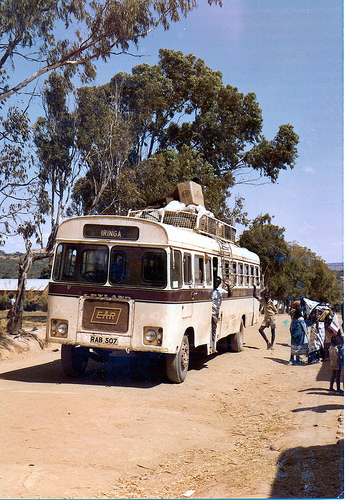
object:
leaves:
[87, 103, 94, 117]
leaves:
[322, 275, 330, 286]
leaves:
[263, 149, 271, 157]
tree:
[5, 71, 130, 336]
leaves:
[113, 130, 120, 140]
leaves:
[237, 119, 247, 130]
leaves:
[180, 159, 189, 180]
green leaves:
[152, 166, 161, 179]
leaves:
[306, 262, 314, 272]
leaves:
[254, 227, 261, 242]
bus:
[45, 197, 263, 382]